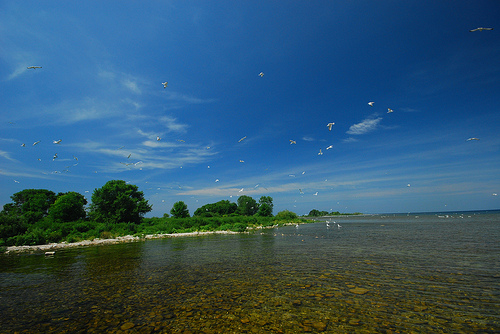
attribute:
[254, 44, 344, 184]
sky — blue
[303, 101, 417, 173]
sky — blue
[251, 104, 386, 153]
sky — blue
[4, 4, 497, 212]
sky — cloudy, blue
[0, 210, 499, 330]
water — shallow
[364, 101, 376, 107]
bird — white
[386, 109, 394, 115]
bird — white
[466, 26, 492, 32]
bird — white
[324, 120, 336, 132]
bird — white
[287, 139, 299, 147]
bird — white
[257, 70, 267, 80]
bird — white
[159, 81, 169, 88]
bird — white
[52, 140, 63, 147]
bird — white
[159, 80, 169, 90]
bird — white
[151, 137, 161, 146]
bird — white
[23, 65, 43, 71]
bird — white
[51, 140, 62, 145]
bird — white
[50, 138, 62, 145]
bird — white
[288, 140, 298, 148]
bird — white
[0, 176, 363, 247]
greenery — lush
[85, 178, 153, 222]
tree — green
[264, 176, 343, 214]
birds — white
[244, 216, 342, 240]
birds — white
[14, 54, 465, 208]
clouds — white